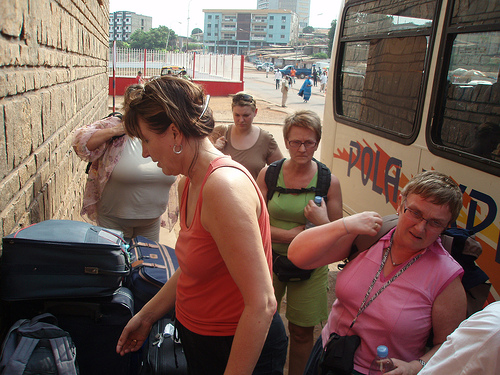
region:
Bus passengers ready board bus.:
[7, 75, 487, 367]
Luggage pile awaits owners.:
[2, 219, 177, 372]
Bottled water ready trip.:
[281, 187, 391, 374]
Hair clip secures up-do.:
[122, 73, 219, 132]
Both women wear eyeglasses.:
[278, 110, 485, 239]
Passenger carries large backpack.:
[354, 171, 494, 305]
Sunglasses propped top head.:
[227, 86, 263, 134]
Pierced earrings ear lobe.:
[129, 93, 197, 174]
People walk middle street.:
[256, 63, 322, 106]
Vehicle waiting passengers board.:
[319, 3, 499, 218]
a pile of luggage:
[1, 207, 200, 372]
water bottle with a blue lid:
[363, 337, 395, 373]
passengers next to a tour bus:
[68, 2, 499, 374]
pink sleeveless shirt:
[311, 211, 461, 371]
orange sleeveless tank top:
[150, 151, 281, 341]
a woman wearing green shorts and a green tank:
[250, 114, 346, 331]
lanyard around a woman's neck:
[336, 221, 443, 341]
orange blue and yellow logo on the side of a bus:
[328, 131, 496, 298]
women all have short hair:
[71, 70, 477, 372]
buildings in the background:
[101, 0, 353, 60]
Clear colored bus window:
[350, 15, 418, 132]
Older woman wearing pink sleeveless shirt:
[323, 196, 464, 355]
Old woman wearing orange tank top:
[154, 176, 273, 343]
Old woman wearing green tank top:
[265, 166, 339, 240]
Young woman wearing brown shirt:
[221, 122, 286, 182]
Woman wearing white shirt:
[79, 115, 176, 241]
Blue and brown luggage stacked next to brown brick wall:
[13, 217, 175, 323]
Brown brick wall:
[21, 40, 97, 114]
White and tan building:
[193, 3, 309, 53]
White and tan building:
[113, 8, 153, 51]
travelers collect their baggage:
[32, 16, 492, 364]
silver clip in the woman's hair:
[180, 79, 227, 141]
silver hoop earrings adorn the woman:
[166, 123, 188, 158]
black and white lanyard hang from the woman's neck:
[365, 237, 427, 350]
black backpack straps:
[270, 153, 340, 208]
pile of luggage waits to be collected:
[27, 218, 174, 372]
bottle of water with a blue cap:
[355, 331, 402, 374]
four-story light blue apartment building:
[197, 3, 309, 56]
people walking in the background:
[254, 38, 324, 105]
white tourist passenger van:
[312, 4, 499, 187]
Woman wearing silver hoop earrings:
[171, 140, 179, 162]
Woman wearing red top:
[189, 232, 243, 338]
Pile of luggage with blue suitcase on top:
[28, 212, 134, 327]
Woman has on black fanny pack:
[268, 245, 335, 302]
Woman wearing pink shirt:
[342, 280, 403, 359]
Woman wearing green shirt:
[278, 187, 323, 269]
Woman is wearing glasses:
[283, 134, 336, 164]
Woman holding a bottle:
[352, 339, 417, 369]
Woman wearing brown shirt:
[224, 109, 281, 191]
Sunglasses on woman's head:
[223, 84, 267, 116]